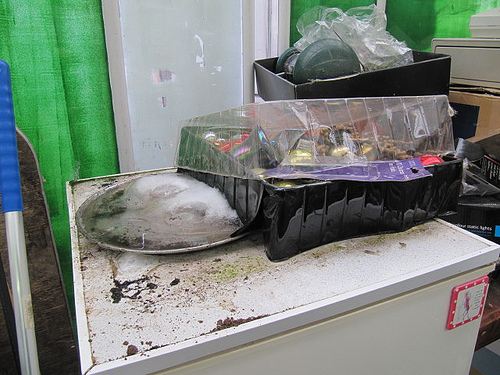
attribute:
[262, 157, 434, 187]
plate —  Purple,  inside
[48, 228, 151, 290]
plate —  Purple,   inside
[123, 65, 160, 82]
plate —   inside,  Purple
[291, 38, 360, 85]
plate —  inside,  Purple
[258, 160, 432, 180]
purple plate —  Purple,  inside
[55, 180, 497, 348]
freezer — small, white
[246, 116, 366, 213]
box — black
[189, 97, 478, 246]
containter — black, plastic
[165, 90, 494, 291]
container — plastic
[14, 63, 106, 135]
curtain — green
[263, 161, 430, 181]
purple plate —  Purple, inside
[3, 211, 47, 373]
silver pole — metal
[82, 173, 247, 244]
plate — inside,  Purple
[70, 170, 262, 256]
plate — full, fuzzy mold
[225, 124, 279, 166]
bell — multicolored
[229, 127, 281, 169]
ornament — christmas